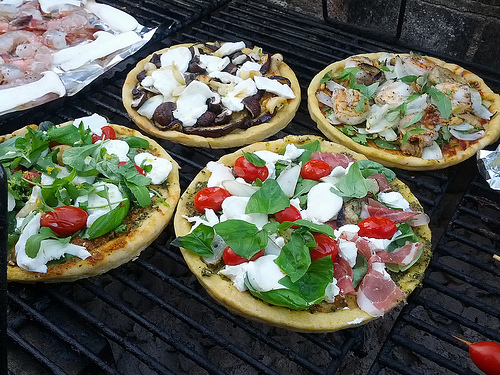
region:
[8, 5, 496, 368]
food on a black table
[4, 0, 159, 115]
shrimps in a plate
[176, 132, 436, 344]
a bowl with salad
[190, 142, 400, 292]
grape tomatoes on a bowl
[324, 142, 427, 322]
slices of meat on salad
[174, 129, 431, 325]
green leaves on salad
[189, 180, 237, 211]
grape tomatoes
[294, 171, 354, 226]
piece of white cheese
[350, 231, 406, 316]
slices of red meat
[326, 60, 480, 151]
shrimps on salad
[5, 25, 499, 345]
pizzas on a grill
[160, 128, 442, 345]
tomatoe and basil pizza on a grill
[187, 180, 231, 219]
tomatoe on a pizza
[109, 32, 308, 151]
mushroom pizza on a grill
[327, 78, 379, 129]
shrimp on a pizza on a grill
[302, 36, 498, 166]
shrimp pizza on a grill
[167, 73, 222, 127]
mozzarella cheese on a pizza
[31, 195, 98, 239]
tomatoe on a pizza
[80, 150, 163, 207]
basil on a pizza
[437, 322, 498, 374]
red radish on a grill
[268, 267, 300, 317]
part of a leaf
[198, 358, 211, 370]
part of a metal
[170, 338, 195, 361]
part of a grill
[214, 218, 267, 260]
fresh basil leaf on salad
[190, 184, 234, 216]
fresh tomato in salad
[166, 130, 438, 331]
salad on flat bread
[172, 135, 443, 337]
bread on grill top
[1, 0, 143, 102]
peeled shrimp in foil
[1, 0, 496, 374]
dirty black grill grate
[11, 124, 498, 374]
coal ashes under grate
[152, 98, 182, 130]
mushroom piece in salad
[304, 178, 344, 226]
slice of mozzarella cheese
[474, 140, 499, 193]
small piece of crumpled foil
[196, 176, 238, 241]
the tomato is red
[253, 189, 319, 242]
the tomato is red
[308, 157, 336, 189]
the tomato is red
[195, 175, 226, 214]
the tomato is red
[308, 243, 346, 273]
the tomato is red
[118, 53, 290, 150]
pizza on the grill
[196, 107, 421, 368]
pizza on the grill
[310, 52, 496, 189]
pizza on the grill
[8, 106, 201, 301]
pizza on the grill